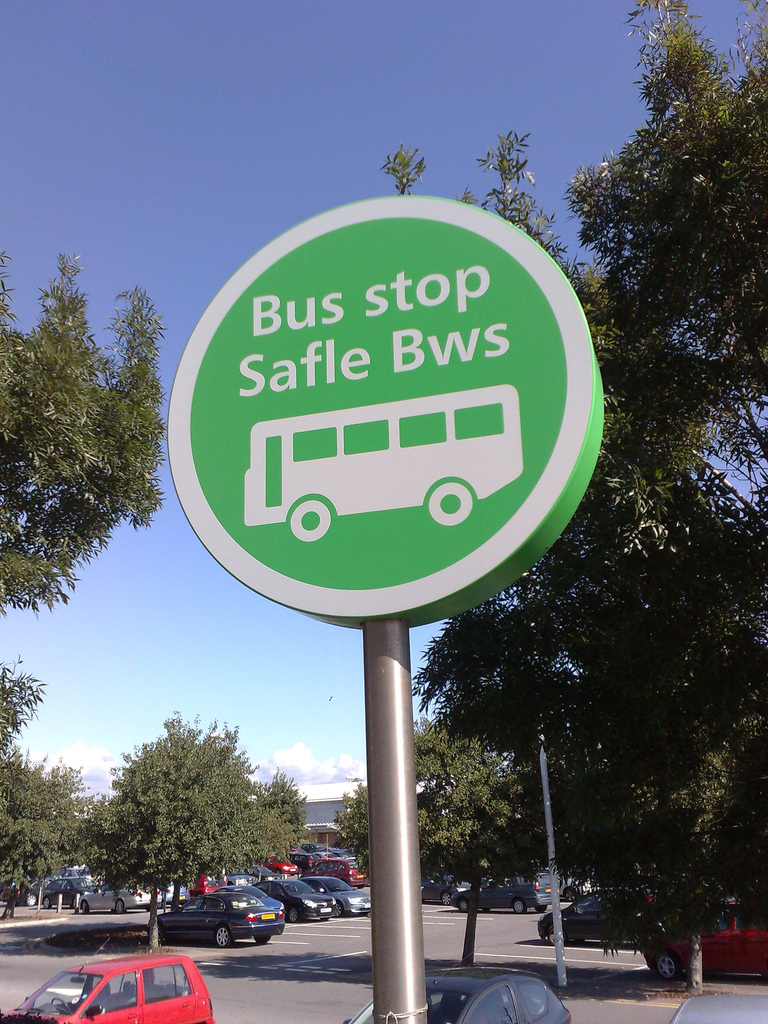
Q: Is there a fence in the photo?
A: No, there are no fences.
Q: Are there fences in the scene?
A: No, there are no fences.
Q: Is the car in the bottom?
A: Yes, the car is in the bottom of the image.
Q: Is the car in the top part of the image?
A: No, the car is in the bottom of the image.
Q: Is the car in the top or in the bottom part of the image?
A: The car is in the bottom of the image.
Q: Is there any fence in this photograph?
A: No, there are no fences.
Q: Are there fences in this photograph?
A: No, there are no fences.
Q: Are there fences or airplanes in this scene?
A: No, there are no fences or airplanes.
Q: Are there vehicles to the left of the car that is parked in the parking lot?
A: Yes, there is a vehicle to the left of the car.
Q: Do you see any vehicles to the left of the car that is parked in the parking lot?
A: Yes, there is a vehicle to the left of the car.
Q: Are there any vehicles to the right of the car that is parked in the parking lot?
A: No, the vehicle is to the left of the car.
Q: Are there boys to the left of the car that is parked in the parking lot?
A: No, there is a vehicle to the left of the car.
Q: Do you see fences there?
A: No, there are no fences.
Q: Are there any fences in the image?
A: No, there are no fences.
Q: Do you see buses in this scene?
A: Yes, there is a bus.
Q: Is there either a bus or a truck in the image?
A: Yes, there is a bus.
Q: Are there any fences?
A: No, there are no fences.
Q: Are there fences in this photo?
A: No, there are no fences.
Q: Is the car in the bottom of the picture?
A: Yes, the car is in the bottom of the image.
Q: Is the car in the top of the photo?
A: No, the car is in the bottom of the image.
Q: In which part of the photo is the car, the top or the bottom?
A: The car is in the bottom of the image.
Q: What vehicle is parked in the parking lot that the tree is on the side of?
A: The vehicle is a car.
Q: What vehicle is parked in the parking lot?
A: The vehicle is a car.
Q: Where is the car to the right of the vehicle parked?
A: The car is parked in the parking lot.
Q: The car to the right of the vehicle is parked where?
A: The car is parked in the parking lot.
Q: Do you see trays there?
A: No, there are no trays.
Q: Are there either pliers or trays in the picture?
A: No, there are no trays or pliers.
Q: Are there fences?
A: No, there are no fences.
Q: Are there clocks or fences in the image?
A: No, there are no fences or clocks.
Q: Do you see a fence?
A: No, there are no fences.